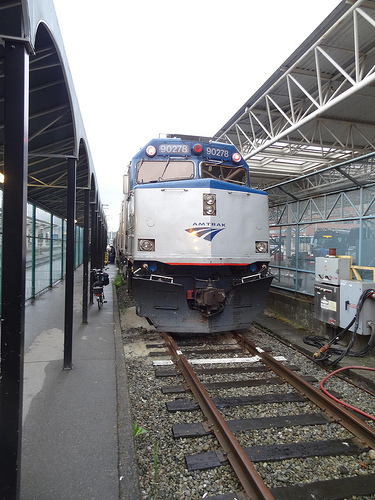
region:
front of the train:
[113, 122, 316, 307]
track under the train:
[210, 333, 304, 447]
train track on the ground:
[167, 347, 337, 483]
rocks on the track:
[218, 371, 289, 425]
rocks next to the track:
[131, 388, 166, 434]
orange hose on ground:
[307, 362, 366, 423]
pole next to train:
[49, 157, 109, 355]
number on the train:
[198, 138, 241, 162]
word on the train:
[186, 209, 234, 236]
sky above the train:
[137, 34, 223, 89]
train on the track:
[125, 127, 278, 340]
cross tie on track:
[188, 434, 363, 457]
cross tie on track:
[213, 414, 316, 431]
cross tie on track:
[209, 390, 303, 408]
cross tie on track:
[199, 381, 282, 390]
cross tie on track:
[188, 368, 265, 377]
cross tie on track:
[184, 356, 248, 364]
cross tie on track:
[174, 345, 236, 353]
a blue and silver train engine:
[112, 136, 273, 332]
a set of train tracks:
[144, 328, 374, 498]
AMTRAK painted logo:
[182, 218, 225, 242]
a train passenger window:
[138, 159, 193, 181]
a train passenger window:
[201, 161, 245, 183]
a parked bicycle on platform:
[89, 266, 109, 310]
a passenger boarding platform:
[21, 258, 129, 499]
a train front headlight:
[146, 144, 156, 155]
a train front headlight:
[232, 152, 241, 162]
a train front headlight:
[136, 239, 154, 251]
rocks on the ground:
[133, 375, 169, 429]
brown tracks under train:
[202, 347, 305, 485]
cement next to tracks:
[55, 366, 105, 433]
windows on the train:
[144, 149, 249, 188]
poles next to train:
[24, 215, 128, 292]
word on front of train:
[187, 206, 234, 234]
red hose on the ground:
[311, 368, 354, 408]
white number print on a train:
[157, 143, 189, 153]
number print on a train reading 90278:
[158, 142, 188, 153]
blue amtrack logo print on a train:
[184, 221, 227, 244]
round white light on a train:
[138, 238, 154, 250]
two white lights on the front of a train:
[136, 237, 269, 254]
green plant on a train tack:
[143, 440, 163, 485]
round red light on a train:
[191, 140, 206, 154]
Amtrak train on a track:
[112, 132, 275, 338]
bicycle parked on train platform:
[89, 260, 109, 313]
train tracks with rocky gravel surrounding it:
[140, 334, 372, 498]